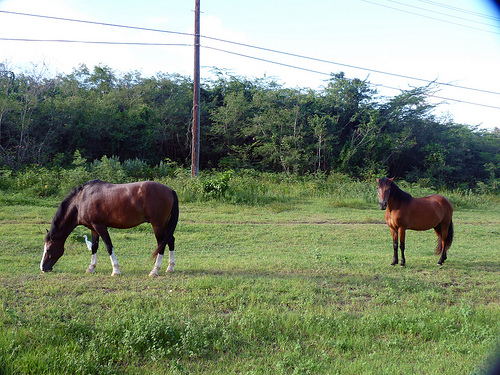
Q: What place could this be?
A: It is a field.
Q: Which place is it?
A: It is a field.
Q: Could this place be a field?
A: Yes, it is a field.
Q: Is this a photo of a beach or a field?
A: It is showing a field.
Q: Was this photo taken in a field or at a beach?
A: It was taken at a field.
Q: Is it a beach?
A: No, it is a field.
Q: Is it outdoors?
A: Yes, it is outdoors.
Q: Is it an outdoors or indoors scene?
A: It is outdoors.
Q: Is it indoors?
A: No, it is outdoors.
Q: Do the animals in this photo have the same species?
A: No, they are horses and birds.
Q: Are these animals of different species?
A: Yes, they are horses and birds.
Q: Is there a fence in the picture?
A: No, there are no fences.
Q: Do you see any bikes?
A: No, there are no bikes.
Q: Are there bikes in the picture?
A: No, there are no bikes.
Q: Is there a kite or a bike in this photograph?
A: No, there are no bikes or kites.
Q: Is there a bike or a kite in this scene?
A: No, there are no bikes or kites.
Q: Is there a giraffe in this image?
A: No, there are no giraffes.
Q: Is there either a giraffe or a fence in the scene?
A: No, there are no giraffes or fences.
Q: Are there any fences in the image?
A: No, there are no fences.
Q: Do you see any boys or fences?
A: No, there are no fences or boys.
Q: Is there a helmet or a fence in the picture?
A: No, there are no fences or helmets.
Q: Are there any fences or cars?
A: No, there are no fences or cars.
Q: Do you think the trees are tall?
A: Yes, the trees are tall.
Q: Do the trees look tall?
A: Yes, the trees are tall.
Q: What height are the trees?
A: The trees are tall.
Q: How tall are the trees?
A: The trees are tall.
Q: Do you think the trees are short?
A: No, the trees are tall.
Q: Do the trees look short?
A: No, the trees are tall.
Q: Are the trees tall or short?
A: The trees are tall.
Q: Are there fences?
A: No, there are no fences.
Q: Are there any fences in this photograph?
A: No, there are no fences.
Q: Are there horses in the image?
A: Yes, there is a horse.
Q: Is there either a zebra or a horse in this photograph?
A: Yes, there is a horse.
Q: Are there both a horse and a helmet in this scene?
A: No, there is a horse but no helmets.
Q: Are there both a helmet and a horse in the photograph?
A: No, there is a horse but no helmets.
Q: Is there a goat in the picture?
A: No, there are no goats.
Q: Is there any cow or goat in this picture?
A: No, there are no goats or cows.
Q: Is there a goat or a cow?
A: No, there are no goats or cows.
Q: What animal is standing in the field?
A: The animal is a horse.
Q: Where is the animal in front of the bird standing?
A: The horse is standing in the field.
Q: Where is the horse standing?
A: The horse is standing in the field.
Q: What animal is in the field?
A: The animal is a horse.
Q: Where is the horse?
A: The horse is in the field.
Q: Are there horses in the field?
A: Yes, there is a horse in the field.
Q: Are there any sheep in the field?
A: No, there is a horse in the field.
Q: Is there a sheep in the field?
A: No, there is a horse in the field.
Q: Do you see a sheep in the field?
A: No, there is a horse in the field.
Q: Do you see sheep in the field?
A: No, there is a horse in the field.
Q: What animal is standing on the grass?
A: The horse is standing on the grass.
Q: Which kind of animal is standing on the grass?
A: The animal is a horse.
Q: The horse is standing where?
A: The horse is standing on the grass.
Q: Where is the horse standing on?
A: The horse is standing on the grass.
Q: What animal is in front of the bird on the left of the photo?
A: The horse is in front of the bird.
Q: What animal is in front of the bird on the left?
A: The horse is in front of the bird.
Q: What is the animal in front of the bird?
A: The animal is a horse.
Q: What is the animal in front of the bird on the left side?
A: The animal is a horse.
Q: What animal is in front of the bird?
A: The animal is a horse.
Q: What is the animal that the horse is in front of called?
A: The animal is a bird.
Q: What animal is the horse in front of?
A: The horse is in front of the bird.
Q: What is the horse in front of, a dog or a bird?
A: The horse is in front of a bird.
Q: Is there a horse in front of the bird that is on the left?
A: Yes, there is a horse in front of the bird.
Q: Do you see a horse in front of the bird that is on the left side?
A: Yes, there is a horse in front of the bird.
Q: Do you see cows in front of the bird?
A: No, there is a horse in front of the bird.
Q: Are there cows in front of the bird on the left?
A: No, there is a horse in front of the bird.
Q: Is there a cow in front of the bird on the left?
A: No, there is a horse in front of the bird.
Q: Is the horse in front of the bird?
A: Yes, the horse is in front of the bird.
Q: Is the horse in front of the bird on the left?
A: Yes, the horse is in front of the bird.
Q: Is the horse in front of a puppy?
A: No, the horse is in front of the bird.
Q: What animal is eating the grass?
A: The horse is eating the grass.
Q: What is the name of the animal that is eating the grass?
A: The animal is a horse.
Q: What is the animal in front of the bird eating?
A: The horse is eating grass.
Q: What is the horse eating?
A: The horse is eating grass.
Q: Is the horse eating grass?
A: Yes, the horse is eating grass.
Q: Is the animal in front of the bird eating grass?
A: Yes, the horse is eating grass.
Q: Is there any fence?
A: No, there are no fences.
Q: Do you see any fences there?
A: No, there are no fences.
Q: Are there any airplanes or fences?
A: No, there are no fences or airplanes.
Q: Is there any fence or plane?
A: No, there are no fences or airplanes.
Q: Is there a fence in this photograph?
A: No, there are no fences.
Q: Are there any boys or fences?
A: No, there are no fences or boys.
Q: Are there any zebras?
A: No, there are no zebras.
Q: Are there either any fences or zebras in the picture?
A: No, there are no zebras or fences.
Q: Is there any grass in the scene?
A: Yes, there is grass.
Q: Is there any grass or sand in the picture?
A: Yes, there is grass.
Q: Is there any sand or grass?
A: Yes, there is grass.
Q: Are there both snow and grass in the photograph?
A: No, there is grass but no snow.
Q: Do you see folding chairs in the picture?
A: No, there are no folding chairs.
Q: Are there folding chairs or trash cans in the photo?
A: No, there are no folding chairs or trash cans.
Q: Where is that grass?
A: The grass is in the field.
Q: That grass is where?
A: The grass is in the field.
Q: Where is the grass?
A: The grass is in the field.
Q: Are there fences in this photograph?
A: No, there are no fences.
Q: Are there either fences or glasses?
A: No, there are no fences or glasses.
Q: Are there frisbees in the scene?
A: No, there are no frisbees.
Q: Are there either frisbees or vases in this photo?
A: No, there are no frisbees or vases.